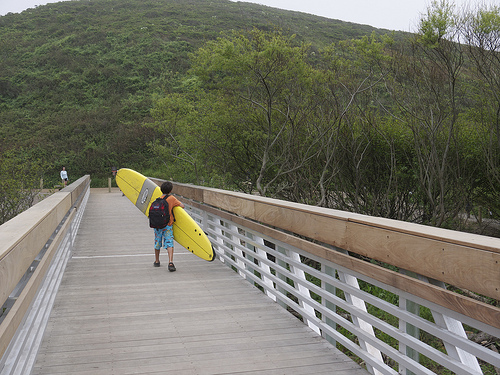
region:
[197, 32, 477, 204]
the trees with sparse leaves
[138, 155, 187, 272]
the boy on the bridge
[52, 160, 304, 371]
the bridge is made of wood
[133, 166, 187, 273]
the boy carrying a surfboard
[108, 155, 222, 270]
the surfboard is yellow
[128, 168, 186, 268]
the boy wearing shorts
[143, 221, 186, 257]
the shorts are blue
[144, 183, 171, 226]
the boy wearing a backpack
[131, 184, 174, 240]
the back pack is black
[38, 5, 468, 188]
the mountain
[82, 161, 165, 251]
the surfing board is yellow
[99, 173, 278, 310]
the surfing board is yellow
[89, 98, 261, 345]
the surfing board is yellow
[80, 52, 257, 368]
the surfing board is yellow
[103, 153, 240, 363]
the surfing board is yellow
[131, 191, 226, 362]
the surfing board is yellow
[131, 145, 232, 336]
the surfing board is yellow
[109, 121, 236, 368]
the surfing board is yellow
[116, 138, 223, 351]
the surfing board is yellow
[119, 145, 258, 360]
the surfing board is yellow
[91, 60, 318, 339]
a boy holding a surfboard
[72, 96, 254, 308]
a boy holding a yellow surfboard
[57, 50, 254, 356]
a boy walking on a bridge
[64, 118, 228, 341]
a boy walking down a bridge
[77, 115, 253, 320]
a boy with a backpack on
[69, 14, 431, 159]
a grassy mountain in distance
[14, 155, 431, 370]
a wooden bridge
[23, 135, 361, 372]
a longer wooden bridge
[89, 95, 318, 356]
a young boy holding surfboard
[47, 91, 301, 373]
a young child with yellow surfboard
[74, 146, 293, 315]
the surfing board is yellow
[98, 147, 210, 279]
little boy carrying a surfboard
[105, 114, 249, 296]
little boy with dark brown hair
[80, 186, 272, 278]
little boy with short hair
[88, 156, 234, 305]
little boy with short sleeve orange shirt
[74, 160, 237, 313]
little boy with blue floral walking shorts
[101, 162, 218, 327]
little boy wearing pair of leather sandles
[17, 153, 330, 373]
little boy walking down a wooden bridge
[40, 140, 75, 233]
person with white shirt on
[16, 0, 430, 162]
beautiful green mountain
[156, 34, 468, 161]
beautiful green trees by the wooden bridge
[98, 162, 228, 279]
boy carrying big board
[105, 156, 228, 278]
boy carrying big board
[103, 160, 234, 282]
boy carrying big board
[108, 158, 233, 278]
boy carrying big board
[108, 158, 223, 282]
boy carrying big board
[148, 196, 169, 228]
A backpack on a boy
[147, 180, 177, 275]
A boy carrying a surfboard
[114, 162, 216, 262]
A yellow surfboard being carried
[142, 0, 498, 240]
Green trees near a bridge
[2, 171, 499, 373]
A bridge outdoors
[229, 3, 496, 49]
Sky behind a mountain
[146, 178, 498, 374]
Railing on a bridge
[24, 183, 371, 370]
Boards on a bridge